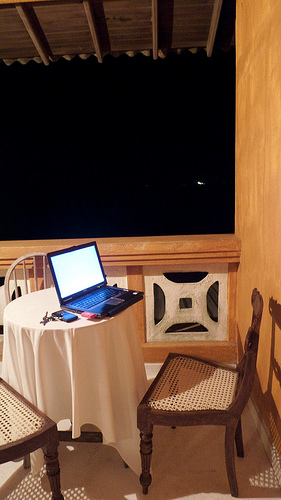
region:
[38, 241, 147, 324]
Laptop that is on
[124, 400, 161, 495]
Wooden chair leg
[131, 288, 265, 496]
Brown chair with holes on seat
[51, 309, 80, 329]
black cell phone sitting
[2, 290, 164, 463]
table with long white cloth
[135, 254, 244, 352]
White design under railing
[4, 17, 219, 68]
Part of the roof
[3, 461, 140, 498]
Shadow of chair on floor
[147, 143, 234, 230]
small light in the dark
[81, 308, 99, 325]
Something red sticking out of laptop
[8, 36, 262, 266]
A pitch black night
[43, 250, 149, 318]
a laptop that is on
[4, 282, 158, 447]
a little round table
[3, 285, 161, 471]
table with white cloth over it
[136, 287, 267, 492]
a chair made of wood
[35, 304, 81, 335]
cell phone and keys on table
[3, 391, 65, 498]
shadow of holes from the seat of chair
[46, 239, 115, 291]
a bright screen on the laptop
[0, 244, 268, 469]
three chairs around the table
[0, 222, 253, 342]
a wood balcony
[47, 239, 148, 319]
Computer sitting on table.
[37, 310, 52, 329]
Keys sitting on table.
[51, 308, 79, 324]
Phone sitting on table.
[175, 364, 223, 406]
Lattice work on chair seat.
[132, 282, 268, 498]
Chair at the table.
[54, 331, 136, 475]
White tablecloth on table.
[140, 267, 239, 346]
Design in balcony wall.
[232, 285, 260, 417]
Back of chair at table.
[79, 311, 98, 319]
Flash drive attached to computer.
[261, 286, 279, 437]
Shadow of chair's back.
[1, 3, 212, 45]
a dark wooden roof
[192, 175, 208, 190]
a light seen in the distance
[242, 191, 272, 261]
dark orange paint on a wall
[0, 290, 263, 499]
two wooden chairs near a table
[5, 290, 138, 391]
white tablecloth on a round table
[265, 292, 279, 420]
chair's shadow on a wall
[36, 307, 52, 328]
set of keys on a table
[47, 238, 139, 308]
black laptop computer on a table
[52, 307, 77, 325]
black phone on a table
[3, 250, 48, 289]
the curved back of a chair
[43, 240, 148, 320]
Black laptop on a table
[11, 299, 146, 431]
A white table cloth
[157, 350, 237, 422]
Wicker chair support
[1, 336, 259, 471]
Two wooden chairs with wicker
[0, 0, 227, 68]
Brown wood awning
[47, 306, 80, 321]
Black cell phone on the table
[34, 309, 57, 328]
A set of keys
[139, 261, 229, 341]
Stone ornate decor on railing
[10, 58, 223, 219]
It is night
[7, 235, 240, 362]
A wood porch railing